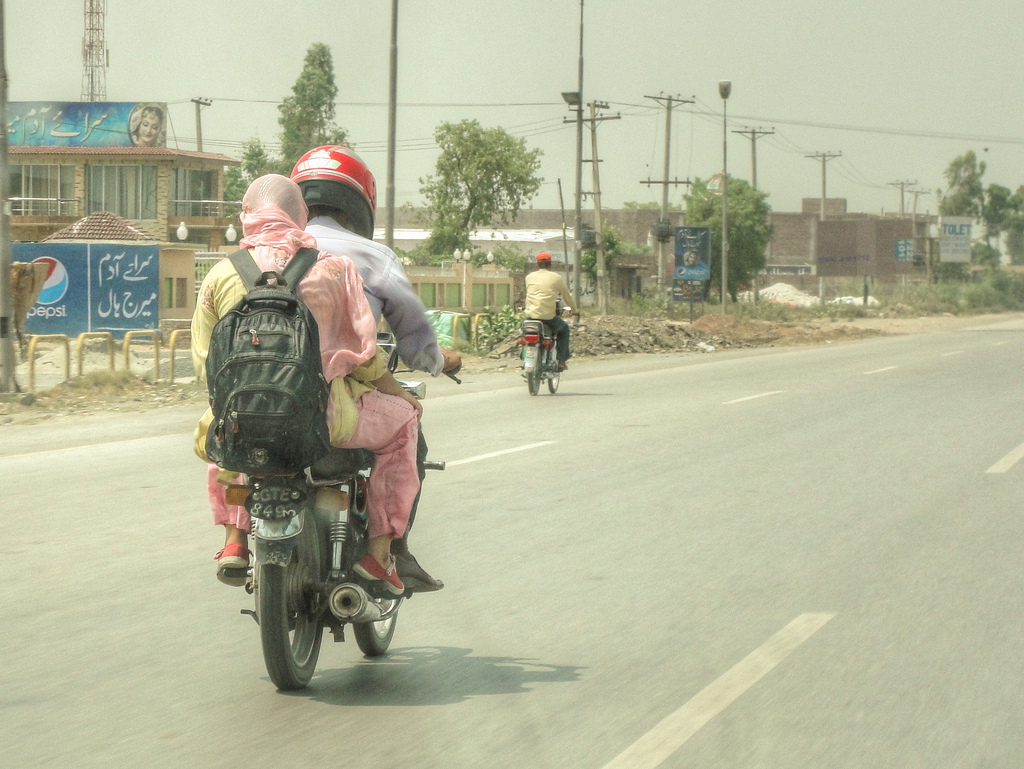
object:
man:
[288, 146, 446, 593]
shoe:
[351, 552, 403, 595]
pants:
[326, 375, 421, 539]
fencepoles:
[28, 329, 190, 396]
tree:
[406, 119, 543, 266]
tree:
[277, 43, 356, 177]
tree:
[222, 137, 291, 217]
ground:
[720, 468, 816, 547]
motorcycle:
[239, 329, 464, 690]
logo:
[30, 256, 69, 306]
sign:
[11, 243, 158, 340]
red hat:
[536, 252, 552, 261]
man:
[525, 253, 579, 371]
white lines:
[595, 610, 838, 766]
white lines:
[985, 444, 1024, 472]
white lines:
[444, 441, 553, 467]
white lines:
[723, 390, 780, 405]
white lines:
[866, 366, 896, 374]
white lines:
[944, 351, 963, 356]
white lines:
[996, 340, 1005, 344]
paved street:
[0, 312, 1024, 769]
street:
[562, 411, 968, 685]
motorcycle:
[517, 306, 578, 395]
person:
[285, 146, 461, 593]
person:
[191, 173, 421, 595]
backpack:
[205, 248, 329, 478]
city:
[0, 0, 1024, 769]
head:
[288, 146, 375, 241]